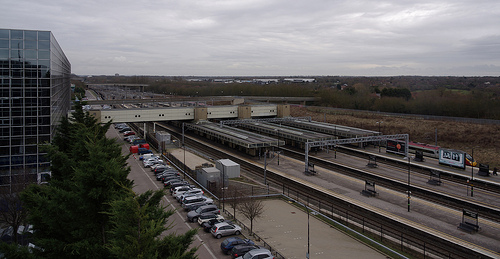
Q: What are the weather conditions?
A: It is cloudy.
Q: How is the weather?
A: It is cloudy.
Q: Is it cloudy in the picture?
A: Yes, it is cloudy.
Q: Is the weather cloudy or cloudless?
A: It is cloudy.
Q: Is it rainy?
A: No, it is cloudy.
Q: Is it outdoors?
A: Yes, it is outdoors.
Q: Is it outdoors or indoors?
A: It is outdoors.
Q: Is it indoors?
A: No, it is outdoors.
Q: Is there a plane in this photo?
A: No, there are no airplanes.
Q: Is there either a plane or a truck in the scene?
A: No, there are no airplanes or trucks.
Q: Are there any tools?
A: No, there are no tools.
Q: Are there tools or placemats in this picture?
A: No, there are no tools or placemats.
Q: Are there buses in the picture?
A: No, there are no buses.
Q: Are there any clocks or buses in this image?
A: No, there are no buses or clocks.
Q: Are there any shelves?
A: No, there are no shelves.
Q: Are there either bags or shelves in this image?
A: No, there are no shelves or bags.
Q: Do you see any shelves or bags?
A: No, there are no shelves or bags.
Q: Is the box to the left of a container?
A: Yes, the box is to the left of a container.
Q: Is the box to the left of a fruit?
A: No, the box is to the left of a container.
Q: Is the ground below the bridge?
A: Yes, the ground is below the bridge.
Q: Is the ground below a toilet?
A: No, the ground is below the bridge.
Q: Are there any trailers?
A: No, there are no trailers.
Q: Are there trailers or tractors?
A: No, there are no trailers or tractors.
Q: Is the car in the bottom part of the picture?
A: Yes, the car is in the bottom of the image.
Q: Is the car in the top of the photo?
A: No, the car is in the bottom of the image.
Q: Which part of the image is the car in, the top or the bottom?
A: The car is in the bottom of the image.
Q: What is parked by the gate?
A: The car is parked by the gate.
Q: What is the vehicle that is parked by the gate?
A: The vehicle is a car.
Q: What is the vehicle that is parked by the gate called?
A: The vehicle is a car.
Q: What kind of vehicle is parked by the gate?
A: The vehicle is a car.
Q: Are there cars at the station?
A: Yes, there is a car at the station.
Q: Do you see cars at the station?
A: Yes, there is a car at the station.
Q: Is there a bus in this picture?
A: No, there are no buses.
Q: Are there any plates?
A: No, there are no plates.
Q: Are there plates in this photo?
A: No, there are no plates.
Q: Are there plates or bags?
A: No, there are no plates or bags.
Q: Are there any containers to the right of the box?
A: Yes, there is a container to the right of the box.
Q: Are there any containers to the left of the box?
A: No, the container is to the right of the box.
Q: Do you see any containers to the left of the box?
A: No, the container is to the right of the box.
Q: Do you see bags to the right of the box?
A: No, there is a container to the right of the box.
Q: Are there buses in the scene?
A: No, there are no buses.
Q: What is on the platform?
A: The sign is on the platform.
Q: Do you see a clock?
A: No, there are no clocks.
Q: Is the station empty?
A: Yes, the station is empty.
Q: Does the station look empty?
A: Yes, the station is empty.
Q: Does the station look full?
A: No, the station is empty.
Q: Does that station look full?
A: No, the station is empty.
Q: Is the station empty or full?
A: The station is empty.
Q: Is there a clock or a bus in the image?
A: No, there are no buses or clocks.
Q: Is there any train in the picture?
A: Yes, there is a train.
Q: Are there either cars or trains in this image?
A: Yes, there is a train.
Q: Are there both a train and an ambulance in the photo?
A: No, there is a train but no ambulances.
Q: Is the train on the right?
A: Yes, the train is on the right of the image.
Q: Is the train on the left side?
A: No, the train is on the right of the image.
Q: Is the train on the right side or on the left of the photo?
A: The train is on the right of the image.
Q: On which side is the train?
A: The train is on the right of the image.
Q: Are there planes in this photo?
A: No, there are no planes.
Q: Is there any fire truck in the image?
A: No, there are no fire trucks.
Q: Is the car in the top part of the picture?
A: No, the car is in the bottom of the image.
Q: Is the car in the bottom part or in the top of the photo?
A: The car is in the bottom of the image.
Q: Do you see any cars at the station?
A: Yes, there is a car at the station.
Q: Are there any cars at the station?
A: Yes, there is a car at the station.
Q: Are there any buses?
A: No, there are no buses.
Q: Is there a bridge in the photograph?
A: Yes, there is a bridge.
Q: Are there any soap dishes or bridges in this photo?
A: Yes, there is a bridge.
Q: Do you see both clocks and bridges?
A: No, there is a bridge but no clocks.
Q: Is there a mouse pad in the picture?
A: No, there are no mouse pads.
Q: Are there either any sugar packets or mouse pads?
A: No, there are no mouse pads or sugar packets.